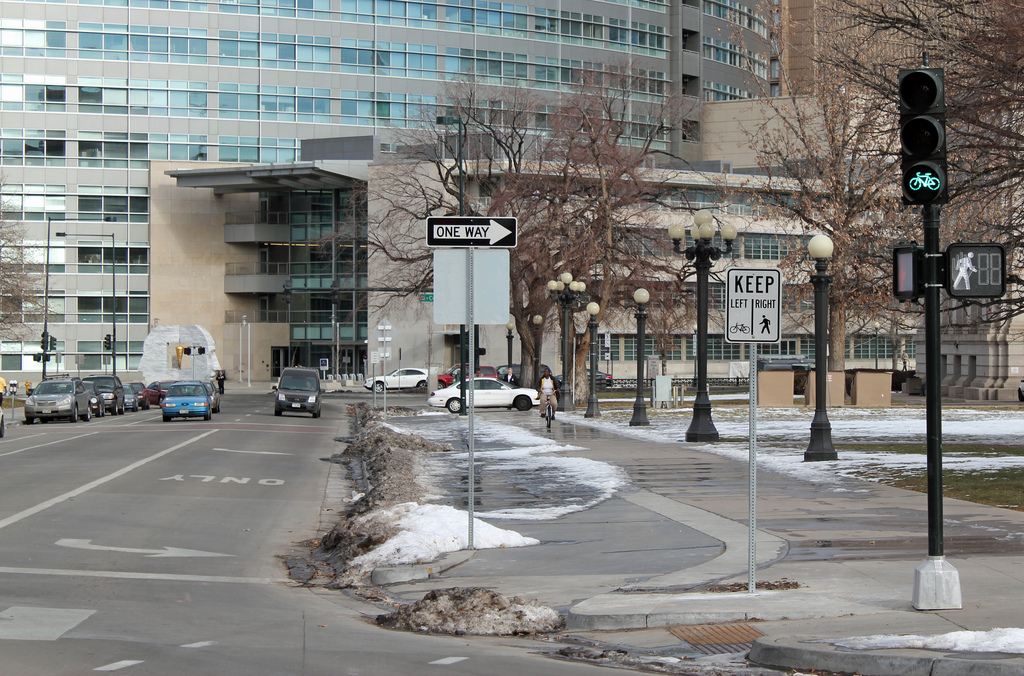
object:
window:
[78, 131, 102, 167]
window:
[297, 87, 314, 122]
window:
[340, 38, 357, 73]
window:
[129, 242, 150, 274]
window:
[103, 186, 128, 222]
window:
[376, 41, 390, 75]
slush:
[274, 402, 452, 587]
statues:
[138, 325, 221, 388]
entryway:
[162, 158, 368, 393]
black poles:
[506, 238, 837, 462]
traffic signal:
[898, 67, 949, 204]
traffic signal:
[893, 242, 1006, 297]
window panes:
[0, 5, 665, 139]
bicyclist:
[467, 408, 1024, 632]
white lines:
[0, 428, 221, 524]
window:
[130, 79, 149, 114]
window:
[488, 51, 501, 85]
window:
[535, 56, 546, 89]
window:
[503, 52, 514, 86]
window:
[103, 241, 128, 274]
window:
[79, 22, 103, 58]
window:
[261, 33, 278, 69]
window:
[408, 43, 423, 78]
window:
[104, 24, 129, 60]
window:
[219, 30, 238, 66]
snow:
[337, 500, 541, 587]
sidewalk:
[351, 407, 725, 611]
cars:
[25, 366, 325, 424]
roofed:
[163, 160, 367, 191]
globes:
[506, 209, 834, 331]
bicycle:
[909, 172, 940, 190]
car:
[553, 369, 612, 390]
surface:
[0, 392, 649, 676]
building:
[0, 0, 779, 386]